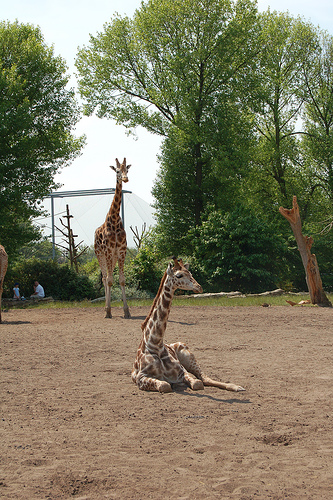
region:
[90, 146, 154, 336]
this is a young giraffe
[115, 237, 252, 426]
this young giraffe is sitting on the ground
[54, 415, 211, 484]
the dirt ground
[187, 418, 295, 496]
there is dirt on the ground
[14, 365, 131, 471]
the ground is covered in dirt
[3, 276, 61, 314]
there are people on a bench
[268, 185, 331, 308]
a wooden tree stump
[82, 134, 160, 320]
this giraffe is standing upright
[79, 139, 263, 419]
there are two giraffes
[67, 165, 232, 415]
giraffes on bare ground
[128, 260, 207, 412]
brown and white spots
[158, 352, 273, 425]
giraffe has white legs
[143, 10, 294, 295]
green and leafy trees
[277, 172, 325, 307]
short and brown tree trunk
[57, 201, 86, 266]
telephone poles in distance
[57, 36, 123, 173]
blue and white sky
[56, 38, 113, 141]
thin clouds in sky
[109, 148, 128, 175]
giraffe has large ossicles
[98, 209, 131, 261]
brown and orange spots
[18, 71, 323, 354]
this is in a zoo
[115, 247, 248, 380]
this is a giraffe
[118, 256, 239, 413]
the giraffe is not in the wild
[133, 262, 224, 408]
this giraffe is smaller than the others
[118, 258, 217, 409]
the giraffe is brown and tan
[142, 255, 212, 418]
the giraffe is laying down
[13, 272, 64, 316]
these are people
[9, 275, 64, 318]
the people are sitting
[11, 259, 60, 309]
the people are watching the giraffes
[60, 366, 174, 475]
the ground here is dirt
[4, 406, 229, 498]
a great big field of dirt.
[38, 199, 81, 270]
street poles with electrical wires.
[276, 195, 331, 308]
a large brown tree stem.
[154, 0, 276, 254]
a huge bunch of trees in the forest.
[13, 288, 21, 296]
a girl is wearing a light blue shirt.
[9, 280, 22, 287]
a lady is wearing a blue hat.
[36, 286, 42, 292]
a man is wearing a white shirt.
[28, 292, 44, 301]
a man is wearing beige pants.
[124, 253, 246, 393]
a giraffe is sitting in the dirt.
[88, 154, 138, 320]
a tall huge giraffe is standing in the forest.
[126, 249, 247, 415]
This is a zebra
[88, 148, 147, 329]
This is a zebra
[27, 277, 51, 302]
This is a person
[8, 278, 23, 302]
This is a person